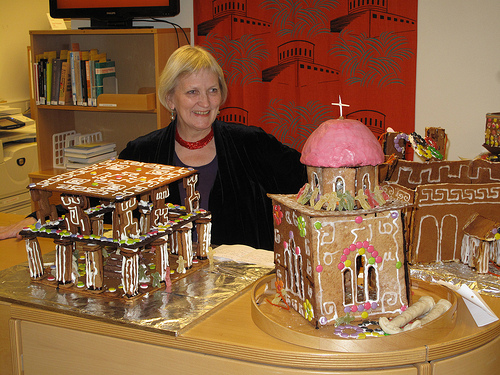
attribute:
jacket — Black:
[139, 121, 340, 291]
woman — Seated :
[118, 28, 328, 283]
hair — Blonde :
[148, 38, 235, 115]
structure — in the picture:
[30, 116, 283, 335]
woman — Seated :
[87, 30, 307, 202]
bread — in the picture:
[253, 180, 433, 328]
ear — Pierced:
[145, 75, 187, 122]